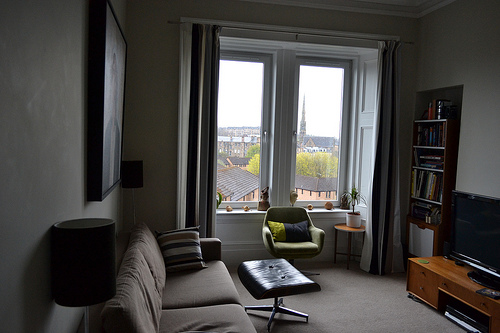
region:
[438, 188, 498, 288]
Black flat screen television on entertainment console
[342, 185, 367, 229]
White potted plant on round table.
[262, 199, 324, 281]
Green upholstered chair near window.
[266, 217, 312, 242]
Green and black pillow in chair.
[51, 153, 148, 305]
Round shaped black lamp shades.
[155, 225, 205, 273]
Brown, black, and grey striped pillow on sofa.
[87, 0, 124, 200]
Painting with black frame hanging on the wall.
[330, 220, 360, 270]
Brown round table near curtains.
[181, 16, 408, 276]
Striped curtain hanging from rod at windows.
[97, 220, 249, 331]
Brown sofa with pillow against wall.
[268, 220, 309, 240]
Green and blue pillow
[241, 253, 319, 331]
Small leather table on the floor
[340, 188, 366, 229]
Plant inside of pot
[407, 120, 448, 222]
Books inside of a bookcase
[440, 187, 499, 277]
Black flat screen television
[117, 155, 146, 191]
Small speaker on the wall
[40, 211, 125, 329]
Round lamp on the right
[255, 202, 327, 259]
Green chair holding a pillow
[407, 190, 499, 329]
Brown entertainment center holding tv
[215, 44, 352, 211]
Two side by side windows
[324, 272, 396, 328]
The floor is made of carpet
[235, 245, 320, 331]
The leather seat on the floor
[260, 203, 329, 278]
The chair is the color green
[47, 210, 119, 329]
The lamp on the table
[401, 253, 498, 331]
The TV stand is made of wood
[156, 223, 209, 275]
The pillow of the couch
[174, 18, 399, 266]
The window has been opened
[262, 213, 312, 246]
The pillow on the chair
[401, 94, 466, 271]
The bookshelf in the wall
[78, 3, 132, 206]
The picture hanging on the wall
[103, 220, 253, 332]
Couch in the living room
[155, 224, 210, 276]
Pillow on the couch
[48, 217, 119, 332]
Lamp in the living room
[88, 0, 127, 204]
Picture hanging on the wall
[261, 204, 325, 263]
Chair in the living room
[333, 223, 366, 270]
Stool in the living room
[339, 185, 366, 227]
Pot plant on the stool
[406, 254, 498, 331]
TV stand in the living room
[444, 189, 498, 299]
TV on the TV stand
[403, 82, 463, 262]
Bookshelf in the living room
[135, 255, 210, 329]
A couch in the room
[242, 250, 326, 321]
A table in the room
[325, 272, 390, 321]
A carpet on the floor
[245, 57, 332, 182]
Glass on the window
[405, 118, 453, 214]
A shelf in the room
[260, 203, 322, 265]
A seat in the room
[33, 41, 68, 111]
A wall in the room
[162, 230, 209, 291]
A pillow on the couch